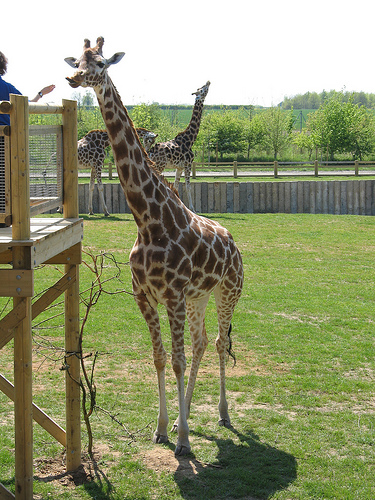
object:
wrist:
[36, 89, 44, 99]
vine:
[54, 247, 127, 495]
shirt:
[2, 80, 25, 126]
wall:
[34, 178, 363, 214]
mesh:
[27, 125, 63, 208]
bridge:
[1, 90, 84, 497]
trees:
[262, 95, 297, 168]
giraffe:
[63, 34, 244, 458]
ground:
[0, 212, 363, 490]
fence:
[33, 177, 363, 211]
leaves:
[319, 107, 354, 132]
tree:
[291, 94, 363, 164]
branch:
[66, 249, 128, 467]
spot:
[136, 443, 199, 479]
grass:
[3, 211, 363, 497]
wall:
[0, 125, 70, 220]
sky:
[4, 3, 363, 107]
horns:
[80, 35, 93, 53]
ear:
[95, 35, 105, 50]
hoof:
[172, 441, 191, 458]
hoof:
[154, 428, 172, 447]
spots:
[148, 205, 199, 284]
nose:
[67, 68, 95, 87]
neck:
[183, 100, 206, 140]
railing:
[5, 90, 84, 237]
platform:
[3, 88, 84, 494]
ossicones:
[81, 32, 103, 50]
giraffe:
[140, 74, 213, 178]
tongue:
[63, 75, 73, 84]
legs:
[210, 261, 231, 429]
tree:
[60, 243, 135, 487]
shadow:
[157, 424, 295, 495]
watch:
[35, 90, 43, 98]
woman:
[3, 51, 54, 237]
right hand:
[40, 83, 55, 96]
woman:
[0, 50, 56, 228]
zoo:
[1, 93, 363, 497]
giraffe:
[40, 125, 157, 219]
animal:
[63, 35, 245, 457]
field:
[24, 108, 363, 171]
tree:
[199, 104, 249, 159]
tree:
[249, 100, 300, 160]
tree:
[308, 87, 363, 162]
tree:
[130, 100, 155, 136]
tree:
[81, 88, 95, 109]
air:
[2, 2, 363, 108]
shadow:
[162, 424, 298, 499]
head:
[143, 132, 157, 153]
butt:
[146, 142, 162, 163]